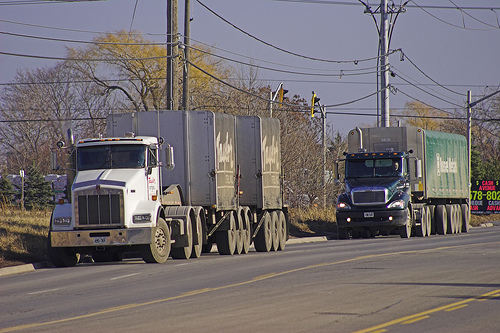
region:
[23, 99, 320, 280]
This is a truck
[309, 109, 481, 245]
This is a truck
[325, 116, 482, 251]
truck on a street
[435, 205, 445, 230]
tire on a truck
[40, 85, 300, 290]
truck on a street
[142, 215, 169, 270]
tire on a truck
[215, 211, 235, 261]
tire on a truck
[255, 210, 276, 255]
tire on a truck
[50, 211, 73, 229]
light on a truck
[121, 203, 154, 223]
light on a tuck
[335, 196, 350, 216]
light on a truck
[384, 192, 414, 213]
light on a truck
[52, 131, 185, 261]
the truck is white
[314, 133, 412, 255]
the truck is blue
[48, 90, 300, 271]
white and grey semi trailer on the side of the road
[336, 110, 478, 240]
green 18 wheel semitrailer parked on the side of the road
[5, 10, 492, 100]
electrical wires and poles on the side of the road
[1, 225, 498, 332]
roadway with yellow pass and no pass lines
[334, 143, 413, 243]
the front of a green eighteen wheel semi trailer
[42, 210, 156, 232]
headlights on a white semi trailer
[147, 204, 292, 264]
nine left side truck tires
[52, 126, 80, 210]
semi trailer exhaust pipe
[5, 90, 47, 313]
grass and trees on the side of the road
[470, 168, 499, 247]
business sign on the side of the road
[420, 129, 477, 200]
green and white truck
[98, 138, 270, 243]
white and gray semi truck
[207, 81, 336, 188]
two yellow and black street signs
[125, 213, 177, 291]
black tire with white rim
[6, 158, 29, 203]
white sign on silver pole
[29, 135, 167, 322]
white and silver front of truck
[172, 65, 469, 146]
electric wires and poles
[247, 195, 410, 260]
four lit uplights on truck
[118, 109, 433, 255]
two semi trucks on road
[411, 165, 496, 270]
bulletin with neon words and numbers